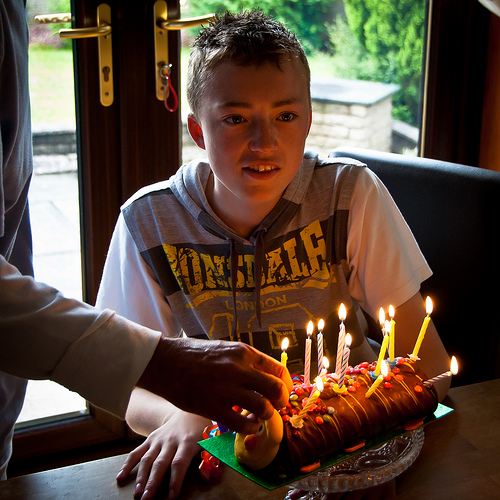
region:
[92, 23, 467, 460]
a boy behind a cake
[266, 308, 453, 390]
many candles on a ckae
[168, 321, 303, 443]
a hand holding a candle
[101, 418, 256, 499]
a hand on the table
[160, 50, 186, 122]
a red loop on the door handle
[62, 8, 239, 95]
two gold door handles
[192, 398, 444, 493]
Glass tray under cake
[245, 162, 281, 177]
white teeth of a boy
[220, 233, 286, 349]
Brown strings from a hood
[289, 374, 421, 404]
colorful dots on a cake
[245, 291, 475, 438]
Birthday candles on a small cake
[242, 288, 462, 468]
Small birthday cake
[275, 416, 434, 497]
Glass ashtray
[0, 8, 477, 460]
A set of double doors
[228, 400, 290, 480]
Face on birthday cake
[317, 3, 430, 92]
Foliage seen through the window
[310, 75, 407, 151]
Small brick wall outside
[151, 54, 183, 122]
Keys stuck in the keyhole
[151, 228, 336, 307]
Design screen printed on T-shirt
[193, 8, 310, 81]
Short spiky hair on a young boy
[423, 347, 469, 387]
this is a lighted candle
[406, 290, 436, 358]
this is a lighted candle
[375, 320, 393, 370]
this is a lighted candle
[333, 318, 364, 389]
this is a lighted candle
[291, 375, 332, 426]
this is a lighted candle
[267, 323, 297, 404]
this is a lighted candle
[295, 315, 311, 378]
this is a lighted candle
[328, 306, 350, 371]
this is a lighted candle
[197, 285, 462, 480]
this is a birthday cake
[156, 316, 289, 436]
the hand of a man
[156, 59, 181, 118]
Key in door lock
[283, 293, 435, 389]
Candles on a birthday cake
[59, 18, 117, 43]
Handle to open door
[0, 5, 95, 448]
Large glass window in a door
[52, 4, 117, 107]
Door latch and handle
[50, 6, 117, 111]
Door lock and latch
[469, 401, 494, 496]
Woodgrain tabletop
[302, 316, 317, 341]
Flame on top of a candle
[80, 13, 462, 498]
Boys celebrating his birthday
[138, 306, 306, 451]
Hand placing candles on the cake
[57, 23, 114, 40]
brass handle on door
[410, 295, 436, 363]
yellow candle on cake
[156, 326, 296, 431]
person's hand touching cake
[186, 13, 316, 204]
smiling face of boy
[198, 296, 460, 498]
birthday cake on platter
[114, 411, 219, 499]
boy's hand on table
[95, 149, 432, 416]
white and gray shirt on boy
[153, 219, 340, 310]
yellow logo on shirt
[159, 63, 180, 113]
key in door lock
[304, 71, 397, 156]
block pillar outside